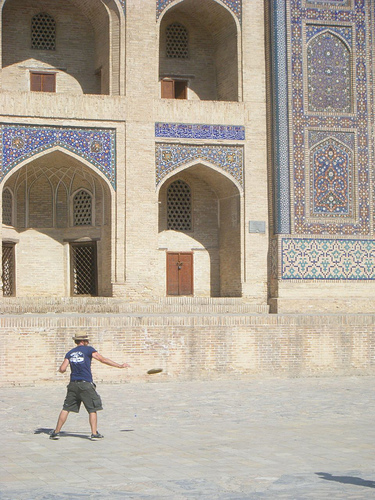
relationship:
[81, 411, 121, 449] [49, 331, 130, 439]
leg on man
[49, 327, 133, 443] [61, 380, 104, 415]
person wearing green pants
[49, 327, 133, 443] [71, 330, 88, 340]
person in hat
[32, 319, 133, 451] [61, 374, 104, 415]
person in green pants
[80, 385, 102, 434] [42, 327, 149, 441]
leg on man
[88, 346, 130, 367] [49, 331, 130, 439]
arm on man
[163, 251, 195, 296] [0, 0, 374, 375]
brown door on beige building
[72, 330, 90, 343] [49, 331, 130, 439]
hat on man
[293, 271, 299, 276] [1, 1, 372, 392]
design on building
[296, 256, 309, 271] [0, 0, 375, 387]
design on beige building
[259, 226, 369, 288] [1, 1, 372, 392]
design on building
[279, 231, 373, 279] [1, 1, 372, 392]
design on building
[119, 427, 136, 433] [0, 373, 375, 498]
shadow on ground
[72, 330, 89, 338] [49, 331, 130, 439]
hat on man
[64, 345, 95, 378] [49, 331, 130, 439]
shirt on man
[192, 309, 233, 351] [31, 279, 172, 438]
wall behind man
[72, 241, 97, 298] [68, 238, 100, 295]
lattice on window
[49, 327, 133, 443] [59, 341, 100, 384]
person in t-shirt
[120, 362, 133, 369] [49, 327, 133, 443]
hand on person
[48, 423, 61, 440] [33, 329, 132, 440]
foot on person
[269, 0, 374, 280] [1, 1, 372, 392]
design on building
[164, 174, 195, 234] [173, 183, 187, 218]
window on holes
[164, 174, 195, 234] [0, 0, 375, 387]
window on beige building